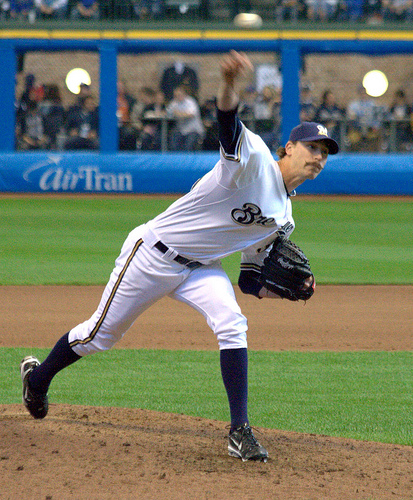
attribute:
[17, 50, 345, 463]
pitcher — right handed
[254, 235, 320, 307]
glove — Black 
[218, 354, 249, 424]
socks — Blue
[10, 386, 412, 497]
mound — covered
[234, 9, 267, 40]
baseball — in the air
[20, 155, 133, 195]
ad — AirTran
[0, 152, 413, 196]
wall — far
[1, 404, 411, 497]
pitcher's mound — dirt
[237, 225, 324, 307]
glove — Black 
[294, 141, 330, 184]
head — man's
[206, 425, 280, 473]
shoe — black 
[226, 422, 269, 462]
foot — planted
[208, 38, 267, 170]
arm — throwing 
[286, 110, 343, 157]
baseball cap — blue 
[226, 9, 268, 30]
ball — in the air 